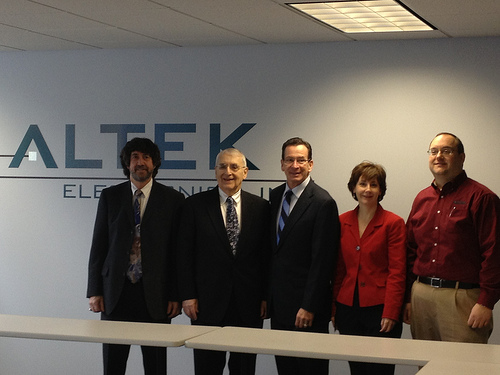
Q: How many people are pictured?
A: Five.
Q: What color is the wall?
A: White.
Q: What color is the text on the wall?
A: Blue.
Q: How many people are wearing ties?
A: Three.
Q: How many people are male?
A: Four.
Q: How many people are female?
A: One.